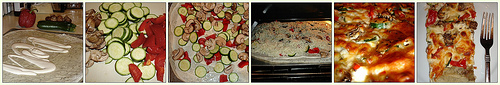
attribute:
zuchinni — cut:
[96, 2, 155, 82]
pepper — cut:
[128, 10, 166, 82]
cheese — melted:
[334, 2, 414, 82]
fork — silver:
[478, 10, 493, 83]